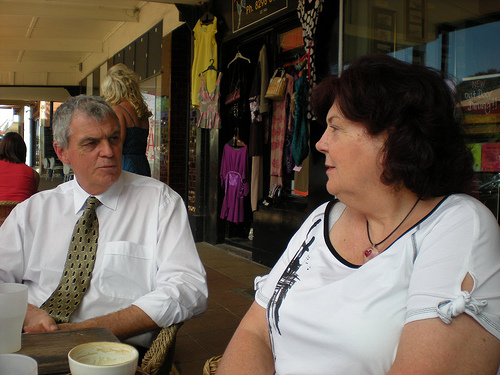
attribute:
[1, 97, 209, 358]
man — talking, grey haired, sitting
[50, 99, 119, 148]
hair — grey, gray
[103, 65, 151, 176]
woman — blond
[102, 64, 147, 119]
hair — blond, long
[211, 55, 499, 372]
woman — talking, sitting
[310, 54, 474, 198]
hair — black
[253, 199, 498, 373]
shirt — white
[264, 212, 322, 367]
design — black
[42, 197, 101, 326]
tie — gold, olive, green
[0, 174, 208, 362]
shirt — white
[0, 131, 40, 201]
woman — brunette, sitting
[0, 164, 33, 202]
shirt — red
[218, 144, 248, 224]
shirt — purple, hanging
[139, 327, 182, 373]
chair — wicker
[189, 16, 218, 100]
dress — hanging, yellow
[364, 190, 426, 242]
necklace — black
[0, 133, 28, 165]
hair — brown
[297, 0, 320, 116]
dress — polka dot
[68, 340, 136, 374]
cup — empty, white, round, large, used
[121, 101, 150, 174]
dress — blue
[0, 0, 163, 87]
roof — beige